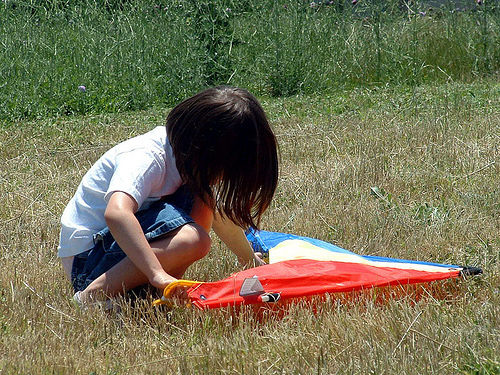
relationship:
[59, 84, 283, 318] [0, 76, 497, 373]
girl in field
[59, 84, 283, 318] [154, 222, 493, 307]
girl with her kite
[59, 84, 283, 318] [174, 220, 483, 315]
girl attending her toy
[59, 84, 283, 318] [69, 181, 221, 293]
girl wearing skirt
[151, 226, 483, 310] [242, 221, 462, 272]
kite has section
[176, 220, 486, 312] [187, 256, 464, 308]
kite has section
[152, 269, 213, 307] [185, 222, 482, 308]
holder for kite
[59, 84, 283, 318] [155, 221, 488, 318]
girl with kite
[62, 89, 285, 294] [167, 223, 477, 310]
girl with kite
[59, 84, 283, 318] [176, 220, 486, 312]
girl with a kite